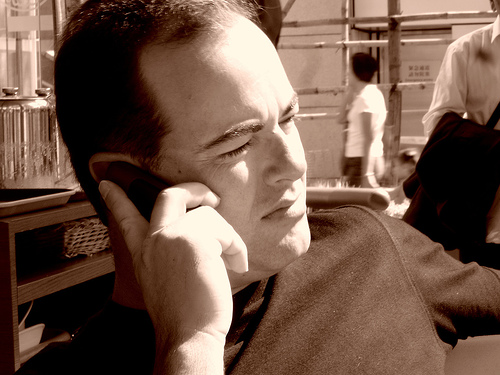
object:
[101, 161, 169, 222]
cell phone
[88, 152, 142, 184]
ear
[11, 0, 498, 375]
man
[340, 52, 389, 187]
person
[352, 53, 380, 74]
hat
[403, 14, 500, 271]
person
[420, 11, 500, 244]
shirt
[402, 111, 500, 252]
coat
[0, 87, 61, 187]
canister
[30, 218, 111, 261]
basket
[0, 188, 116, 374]
shelf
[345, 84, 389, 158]
shirt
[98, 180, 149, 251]
finger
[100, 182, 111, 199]
fingernail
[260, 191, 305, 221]
mouth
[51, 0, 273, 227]
hair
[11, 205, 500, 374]
shirt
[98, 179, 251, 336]
hand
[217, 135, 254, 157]
eye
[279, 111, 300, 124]
eye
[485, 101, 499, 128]
bag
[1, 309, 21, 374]
back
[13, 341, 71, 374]
chair